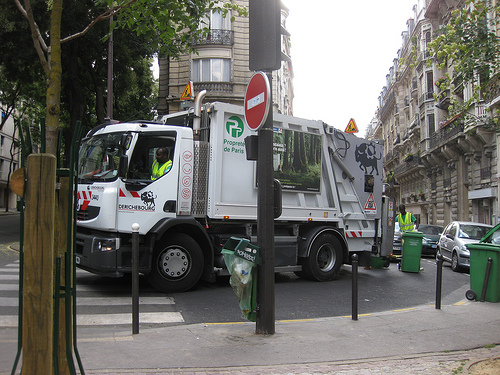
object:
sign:
[243, 71, 270, 133]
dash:
[246, 91, 264, 111]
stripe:
[129, 190, 141, 198]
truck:
[72, 89, 385, 294]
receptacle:
[319, 119, 394, 256]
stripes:
[0, 295, 177, 307]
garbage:
[396, 229, 424, 275]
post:
[253, 67, 274, 336]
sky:
[281, 0, 419, 139]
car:
[434, 219, 500, 272]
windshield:
[76, 134, 127, 178]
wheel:
[143, 231, 206, 294]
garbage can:
[463, 221, 500, 304]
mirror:
[118, 154, 128, 179]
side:
[100, 100, 387, 294]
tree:
[0, 3, 204, 169]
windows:
[189, 56, 234, 82]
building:
[155, 0, 296, 118]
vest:
[150, 159, 173, 181]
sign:
[344, 118, 360, 133]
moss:
[45, 3, 61, 129]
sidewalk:
[0, 298, 499, 375]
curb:
[0, 297, 475, 341]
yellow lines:
[391, 308, 414, 313]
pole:
[131, 223, 139, 335]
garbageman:
[393, 203, 419, 233]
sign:
[179, 81, 194, 101]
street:
[1, 248, 473, 339]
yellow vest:
[397, 212, 415, 233]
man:
[150, 145, 174, 180]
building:
[363, 0, 500, 232]